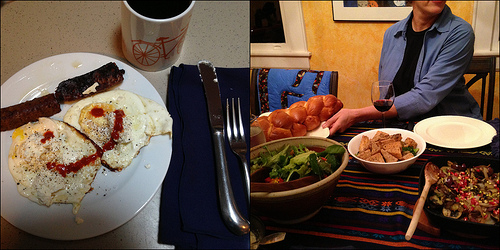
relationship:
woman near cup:
[342, 0, 490, 128] [363, 75, 399, 122]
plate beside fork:
[2, 48, 174, 244] [218, 96, 258, 211]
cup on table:
[363, 75, 399, 122] [255, 101, 499, 249]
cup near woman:
[363, 75, 399, 122] [342, 0, 490, 128]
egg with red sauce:
[63, 88, 172, 170] [88, 103, 108, 121]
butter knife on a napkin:
[199, 59, 255, 231] [154, 65, 251, 244]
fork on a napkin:
[224, 95, 250, 207] [154, 65, 251, 244]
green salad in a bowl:
[252, 147, 326, 177] [250, 132, 347, 217]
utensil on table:
[400, 160, 441, 240] [332, 116, 482, 247]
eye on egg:
[34, 124, 60, 150] [8, 115, 102, 206]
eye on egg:
[86, 103, 107, 121] [63, 85, 173, 168]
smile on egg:
[45, 109, 125, 177] [63, 88, 172, 170]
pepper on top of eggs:
[57, 124, 102, 147] [10, 92, 169, 203]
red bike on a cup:
[129, 38, 181, 65] [116, 0, 195, 71]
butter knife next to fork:
[199, 59, 255, 231] [223, 95, 251, 203]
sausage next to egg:
[56, 60, 123, 103] [57, 85, 173, 173]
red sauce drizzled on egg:
[98, 108, 128, 152] [62, 91, 167, 171]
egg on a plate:
[63, 88, 172, 170] [2, 48, 174, 244]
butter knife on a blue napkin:
[199, 59, 255, 231] [156, 64, 252, 244]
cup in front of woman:
[367, 75, 399, 127] [342, 0, 490, 128]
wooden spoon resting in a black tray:
[403, 156, 440, 241] [424, 162, 484, 244]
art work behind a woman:
[332, 0, 402, 20] [319, 2, 475, 142]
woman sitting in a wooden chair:
[342, 0, 490, 128] [443, 50, 485, 111]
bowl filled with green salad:
[249, 134, 350, 223] [251, 143, 342, 180]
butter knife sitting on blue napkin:
[199, 59, 255, 231] [156, 64, 252, 249]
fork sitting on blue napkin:
[224, 95, 257, 211] [156, 64, 252, 249]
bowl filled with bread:
[346, 124, 427, 175] [355, 129, 417, 164]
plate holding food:
[2, 48, 174, 244] [1, 60, 170, 210]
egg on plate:
[8, 115, 102, 206] [2, 48, 174, 244]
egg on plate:
[63, 88, 154, 170] [2, 48, 174, 244]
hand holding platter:
[315, 103, 354, 141] [252, 104, 334, 140]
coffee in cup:
[126, 1, 193, 21] [116, 0, 195, 71]